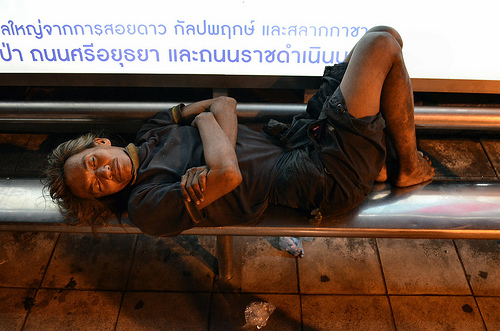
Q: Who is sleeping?
A: A man.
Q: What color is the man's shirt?
A: Black.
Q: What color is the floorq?
A: Brown.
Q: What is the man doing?
A: Sleeping.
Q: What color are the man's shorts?
A: Black.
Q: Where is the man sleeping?
A: A bench.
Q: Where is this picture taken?
A: A station.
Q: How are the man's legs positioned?
A: Crossed.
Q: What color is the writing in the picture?
A: Blue.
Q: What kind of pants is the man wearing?
A: Shorts.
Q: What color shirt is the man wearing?
A: Black.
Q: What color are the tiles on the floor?
A: Brown.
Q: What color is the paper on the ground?
A: White.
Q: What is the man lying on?
A: Bench.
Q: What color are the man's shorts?
A: Black.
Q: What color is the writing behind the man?
A: Blue.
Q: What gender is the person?
A: Male.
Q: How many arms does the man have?
A: 2.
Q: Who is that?
A: A young man.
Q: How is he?
A: Sleeping.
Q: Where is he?
A: On a bench.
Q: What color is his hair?
A: Blondish brown.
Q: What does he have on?
A: Shorts.